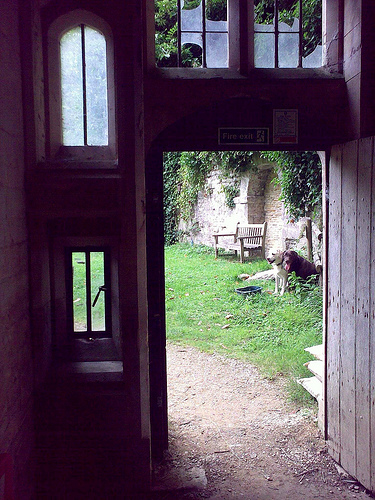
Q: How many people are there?
A: None.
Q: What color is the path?
A: Brown.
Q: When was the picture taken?
A: Daytime.